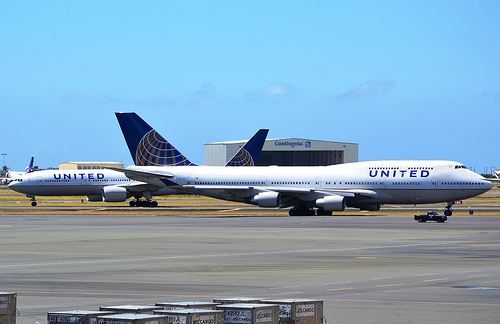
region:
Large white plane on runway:
[108, 109, 491, 216]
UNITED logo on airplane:
[363, 166, 428, 179]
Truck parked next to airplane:
[407, 207, 448, 222]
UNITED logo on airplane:
[50, 170, 111, 177]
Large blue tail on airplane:
[112, 110, 192, 163]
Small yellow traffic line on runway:
[368, 280, 405, 289]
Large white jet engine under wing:
[317, 191, 347, 214]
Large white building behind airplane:
[201, 133, 362, 163]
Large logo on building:
[270, 136, 310, 148]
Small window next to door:
[440, 179, 445, 186]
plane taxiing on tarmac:
[74, 100, 495, 238]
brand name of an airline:
[362, 163, 435, 182]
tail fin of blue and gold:
[112, 106, 207, 166]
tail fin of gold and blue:
[114, 106, 218, 168]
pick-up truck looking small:
[405, 203, 452, 224]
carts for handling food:
[42, 281, 334, 321]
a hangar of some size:
[196, 118, 374, 180]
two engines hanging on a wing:
[232, 190, 352, 212]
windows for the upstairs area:
[359, 163, 436, 173]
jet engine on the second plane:
[99, 184, 129, 205]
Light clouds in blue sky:
[79, 68, 403, 110]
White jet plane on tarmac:
[100, 113, 491, 212]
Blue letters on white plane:
[370, 167, 432, 178]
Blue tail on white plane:
[111, 110, 191, 165]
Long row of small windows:
[187, 180, 487, 186]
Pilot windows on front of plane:
[453, 163, 465, 173]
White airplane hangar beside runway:
[207, 130, 359, 201]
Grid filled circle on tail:
[135, 126, 187, 164]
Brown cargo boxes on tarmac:
[45, 275, 325, 322]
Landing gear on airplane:
[443, 200, 455, 214]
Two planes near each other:
[12, 110, 477, 245]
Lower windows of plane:
[271, 177, 488, 194]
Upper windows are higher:
[358, 154, 451, 181]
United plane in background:
[15, 166, 150, 209]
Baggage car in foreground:
[40, 285, 352, 322]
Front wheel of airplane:
[433, 193, 466, 226]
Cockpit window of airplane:
[448, 151, 468, 178]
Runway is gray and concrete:
[8, 208, 494, 321]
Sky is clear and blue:
[10, 14, 499, 148]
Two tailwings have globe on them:
[107, 102, 273, 162]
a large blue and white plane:
[112, 109, 487, 213]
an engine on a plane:
[314, 194, 344, 211]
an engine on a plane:
[250, 190, 280, 207]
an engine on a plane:
[101, 183, 129, 202]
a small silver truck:
[219, 301, 279, 322]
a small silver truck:
[262, 294, 327, 322]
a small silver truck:
[47, 308, 114, 322]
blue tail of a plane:
[113, 110, 194, 165]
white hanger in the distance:
[202, 134, 357, 174]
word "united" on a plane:
[52, 170, 102, 179]